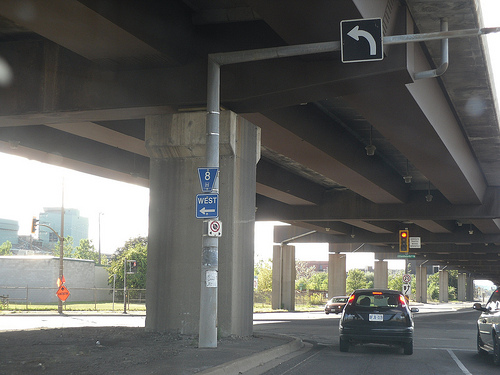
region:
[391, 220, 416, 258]
street light under bridge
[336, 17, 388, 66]
a sign signifying left turn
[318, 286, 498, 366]
multiple cars stopped at street light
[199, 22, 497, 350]
pole for displaying signs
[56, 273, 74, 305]
detour sign on pole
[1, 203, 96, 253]
tall buildings in background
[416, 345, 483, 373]
boundary markers painted on street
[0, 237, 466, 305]
green foilage in traffic area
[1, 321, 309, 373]
concrete island dividing sides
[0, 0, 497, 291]
bridge road over street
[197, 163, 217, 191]
the blue and white street sign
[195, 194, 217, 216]
the blue and white street sign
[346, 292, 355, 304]
the red light on the car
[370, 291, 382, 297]
the red light on the car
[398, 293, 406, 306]
the red light on the car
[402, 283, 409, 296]
the black and white sign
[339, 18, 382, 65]
the black and white sign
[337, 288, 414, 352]
the black stopped car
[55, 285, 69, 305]
the black and orange street sign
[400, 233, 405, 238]
the red traffic light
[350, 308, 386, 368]
this is a car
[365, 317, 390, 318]
this is a plate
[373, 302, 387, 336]
the plate is white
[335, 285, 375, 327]
this is a window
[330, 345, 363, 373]
this is a wheel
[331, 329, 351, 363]
the wheel is black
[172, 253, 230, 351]
this is a pole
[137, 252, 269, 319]
the pole is metal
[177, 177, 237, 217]
this is a sign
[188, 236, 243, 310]
the sign is blue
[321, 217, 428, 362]
Car is stopped at a red light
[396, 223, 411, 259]
The traffic light is red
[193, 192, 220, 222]
West is left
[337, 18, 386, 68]
This is a turn left sign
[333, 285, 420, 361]
The car's brake lights are on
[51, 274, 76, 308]
This is a construction sign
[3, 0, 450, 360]
The car is under an overpass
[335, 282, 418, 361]
The car is black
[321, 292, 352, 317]
The car's headlights are on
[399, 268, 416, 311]
Traffic signs are in front of the car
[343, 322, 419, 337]
BACK BUMPER OF MOVING CAR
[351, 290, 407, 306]
BACK WINDSHIELD OF CAR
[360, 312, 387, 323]
LICENSE TAG OF CAR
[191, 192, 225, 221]
BLUE DIRECTIONAL TRAFFIC SIGN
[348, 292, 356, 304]
REAR BRAKE LIGHT OF CAR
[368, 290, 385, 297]
REAR BRAKE LIGHT OF CAR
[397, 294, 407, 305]
REAR BRAKE LIGHT OF CAR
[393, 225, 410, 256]
OVERHEAD TRAFFIC SIGNAL FOR CARS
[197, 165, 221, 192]
BLUE AISLE SIGN FOR TRAFFI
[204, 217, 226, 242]
WHITE TRAFFIC SIGN FOR CARS